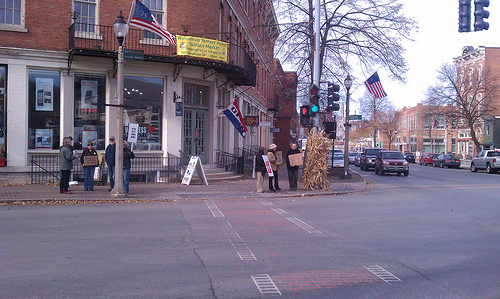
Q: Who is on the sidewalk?
A: People.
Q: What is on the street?
A: Cars.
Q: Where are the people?
A: Sidewalk.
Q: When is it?
A: Day time.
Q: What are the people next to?
A: Building.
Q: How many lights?
A: 1.